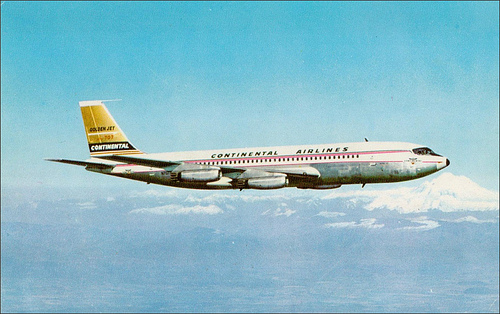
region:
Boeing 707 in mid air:
[81, 100, 498, 212]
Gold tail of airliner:
[65, 102, 137, 177]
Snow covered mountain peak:
[402, 170, 497, 227]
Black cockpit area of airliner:
[406, 137, 436, 163]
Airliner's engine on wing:
[164, 165, 228, 191]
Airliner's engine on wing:
[248, 172, 293, 196]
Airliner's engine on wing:
[306, 181, 344, 196]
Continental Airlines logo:
[209, 145, 374, 157]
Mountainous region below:
[21, 212, 421, 311]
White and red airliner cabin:
[121, 153, 372, 177]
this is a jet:
[66, 98, 434, 205]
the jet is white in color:
[378, 154, 410, 168]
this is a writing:
[212, 144, 354, 158]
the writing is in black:
[211, 147, 281, 158]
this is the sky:
[154, 18, 418, 90]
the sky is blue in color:
[178, 35, 240, 59]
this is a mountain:
[131, 222, 441, 309]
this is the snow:
[438, 175, 490, 206]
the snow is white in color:
[422, 179, 469, 195]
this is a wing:
[106, 153, 214, 183]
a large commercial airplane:
[37, 64, 471, 216]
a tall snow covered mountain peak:
[388, 169, 498, 229]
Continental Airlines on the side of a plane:
[203, 144, 350, 159]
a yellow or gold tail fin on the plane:
[56, 90, 145, 159]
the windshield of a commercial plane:
[409, 142, 431, 155]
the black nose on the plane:
[445, 153, 451, 166]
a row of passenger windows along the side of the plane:
[185, 152, 364, 167]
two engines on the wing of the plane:
[172, 163, 288, 195]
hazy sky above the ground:
[15, 225, 482, 307]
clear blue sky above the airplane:
[150, 7, 478, 100]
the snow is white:
[453, 188, 463, 210]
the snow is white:
[431, 191, 441, 201]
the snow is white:
[457, 178, 463, 201]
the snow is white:
[447, 173, 459, 199]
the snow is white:
[450, 188, 460, 197]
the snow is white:
[457, 188, 462, 200]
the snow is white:
[442, 189, 453, 208]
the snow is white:
[437, 183, 448, 197]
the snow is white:
[458, 177, 468, 202]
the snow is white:
[462, 171, 472, 198]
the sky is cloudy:
[183, 225, 280, 300]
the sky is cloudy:
[165, 210, 315, 310]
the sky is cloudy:
[128, 180, 248, 276]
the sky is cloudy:
[211, 206, 284, 276]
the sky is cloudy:
[268, 185, 425, 306]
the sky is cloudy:
[192, 150, 347, 253]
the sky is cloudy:
[273, 182, 390, 253]